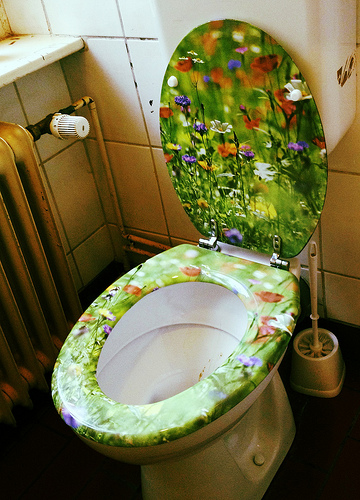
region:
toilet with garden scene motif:
[60, 74, 335, 473]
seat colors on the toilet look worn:
[59, 194, 278, 406]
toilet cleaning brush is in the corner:
[275, 195, 344, 400]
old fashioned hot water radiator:
[0, 148, 86, 274]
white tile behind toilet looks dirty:
[97, 23, 157, 156]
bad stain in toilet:
[163, 339, 226, 385]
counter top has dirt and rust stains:
[0, 15, 82, 81]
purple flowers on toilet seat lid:
[157, 87, 240, 163]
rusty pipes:
[24, 105, 169, 251]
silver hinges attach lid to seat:
[172, 218, 301, 282]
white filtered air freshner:
[48, 108, 91, 146]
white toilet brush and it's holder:
[289, 236, 348, 404]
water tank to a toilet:
[144, 0, 356, 163]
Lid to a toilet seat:
[154, 18, 331, 260]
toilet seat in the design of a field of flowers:
[44, 242, 305, 452]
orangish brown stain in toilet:
[188, 354, 215, 381]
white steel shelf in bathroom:
[1, 33, 89, 75]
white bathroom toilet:
[42, 233, 313, 494]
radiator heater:
[0, 117, 82, 415]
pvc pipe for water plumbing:
[28, 106, 160, 255]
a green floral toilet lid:
[147, 12, 333, 265]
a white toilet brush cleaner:
[292, 232, 348, 395]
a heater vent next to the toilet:
[2, 117, 85, 483]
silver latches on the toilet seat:
[185, 228, 299, 278]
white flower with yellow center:
[209, 114, 235, 134]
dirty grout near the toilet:
[78, 13, 159, 106]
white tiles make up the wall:
[19, 0, 180, 216]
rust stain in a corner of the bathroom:
[0, 10, 33, 56]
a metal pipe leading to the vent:
[24, 88, 142, 255]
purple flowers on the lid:
[169, 94, 215, 142]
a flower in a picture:
[252, 158, 280, 227]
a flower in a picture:
[223, 220, 241, 238]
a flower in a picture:
[181, 152, 193, 185]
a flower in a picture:
[167, 139, 178, 157]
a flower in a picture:
[212, 113, 237, 145]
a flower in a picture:
[216, 142, 242, 163]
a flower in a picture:
[273, 84, 301, 116]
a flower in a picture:
[177, 47, 206, 114]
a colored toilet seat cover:
[147, 10, 328, 269]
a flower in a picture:
[71, 305, 117, 351]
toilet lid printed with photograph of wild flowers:
[160, 21, 326, 254]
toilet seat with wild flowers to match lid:
[51, 243, 297, 446]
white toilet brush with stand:
[290, 244, 340, 397]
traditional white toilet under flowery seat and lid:
[79, 358, 309, 497]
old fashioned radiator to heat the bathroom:
[3, 97, 118, 410]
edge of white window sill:
[0, 33, 85, 91]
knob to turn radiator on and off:
[51, 109, 88, 140]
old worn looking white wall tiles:
[5, 2, 356, 351]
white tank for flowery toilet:
[154, 4, 356, 151]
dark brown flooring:
[14, 264, 359, 497]